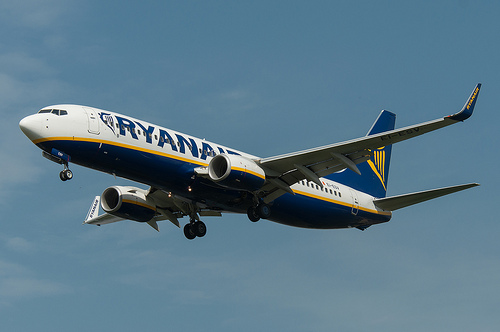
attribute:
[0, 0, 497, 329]
sky — blue 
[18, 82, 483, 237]
jet — white, blue and yellow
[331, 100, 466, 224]
tail — blue and yellow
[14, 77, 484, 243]
airplane — big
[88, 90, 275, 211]
lettering — blue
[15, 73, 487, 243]
plane — white, flying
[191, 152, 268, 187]
engine — cylinder-shaped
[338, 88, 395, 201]
tail — blue, yellow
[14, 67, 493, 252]
airplane — white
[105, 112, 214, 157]
writings — some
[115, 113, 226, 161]
writing — bold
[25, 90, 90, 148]
cockpit — plane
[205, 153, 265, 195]
engine — painted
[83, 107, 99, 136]
door — entry